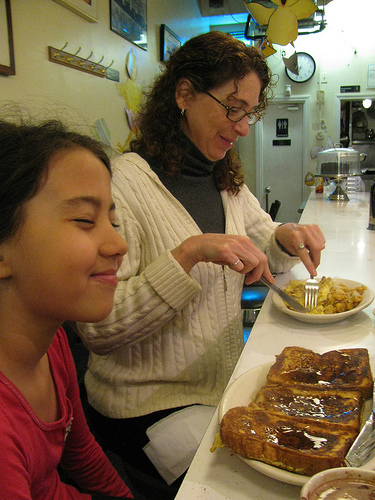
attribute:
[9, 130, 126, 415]
girl — smiling, young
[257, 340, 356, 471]
toast — pieces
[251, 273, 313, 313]
knife — silver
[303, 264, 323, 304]
fork — silver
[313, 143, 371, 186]
cake pan — clear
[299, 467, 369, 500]
cup — hot cocoa, hot chocolate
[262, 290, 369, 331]
bowl — white, small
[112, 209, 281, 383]
sweater — white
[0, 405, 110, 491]
shirt — red, pink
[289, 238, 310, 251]
ring — silver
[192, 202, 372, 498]
table — part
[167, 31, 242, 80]
hair — brown, curly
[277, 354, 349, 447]
french toast — three pieces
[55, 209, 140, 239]
eyes — closed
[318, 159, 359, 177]
cake — chocolate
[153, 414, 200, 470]
napkin — paper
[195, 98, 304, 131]
glasses — brown, framed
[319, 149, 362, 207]
stand — silver